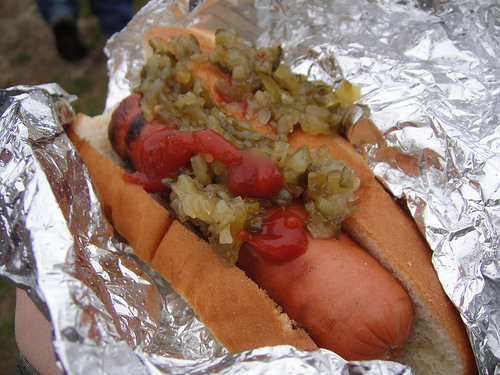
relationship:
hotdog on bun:
[110, 91, 414, 359] [68, 26, 482, 370]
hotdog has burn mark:
[110, 91, 414, 359] [123, 114, 144, 146]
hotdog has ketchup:
[110, 91, 414, 359] [140, 132, 308, 259]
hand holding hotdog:
[12, 291, 50, 374] [110, 91, 414, 359]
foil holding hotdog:
[3, 1, 498, 374] [110, 91, 414, 359]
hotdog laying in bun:
[110, 91, 414, 359] [68, 26, 482, 370]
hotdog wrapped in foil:
[110, 91, 414, 359] [3, 1, 498, 374]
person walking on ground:
[36, 1, 124, 59] [2, 1, 108, 85]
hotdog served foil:
[110, 91, 414, 359] [3, 1, 498, 374]